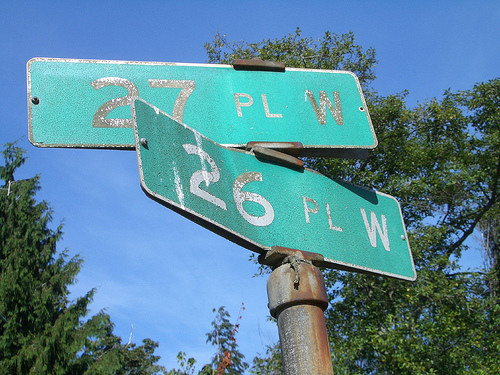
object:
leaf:
[377, 318, 417, 353]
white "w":
[360, 206, 392, 251]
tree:
[202, 36, 496, 374]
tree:
[0, 138, 167, 373]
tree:
[196, 301, 249, 373]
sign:
[25, 54, 379, 150]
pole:
[266, 265, 333, 373]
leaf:
[55, 230, 64, 242]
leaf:
[449, 247, 461, 259]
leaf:
[39, 207, 46, 215]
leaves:
[12, 191, 39, 209]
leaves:
[473, 93, 498, 113]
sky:
[368, 35, 475, 81]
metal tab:
[260, 245, 322, 261]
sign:
[133, 96, 417, 281]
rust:
[280, 255, 315, 264]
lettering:
[305, 91, 343, 126]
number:
[233, 172, 275, 227]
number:
[149, 78, 197, 124]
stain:
[299, 266, 335, 371]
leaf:
[86, 347, 96, 360]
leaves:
[431, 299, 449, 325]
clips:
[252, 144, 305, 167]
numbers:
[90, 75, 138, 129]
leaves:
[21, 267, 35, 281]